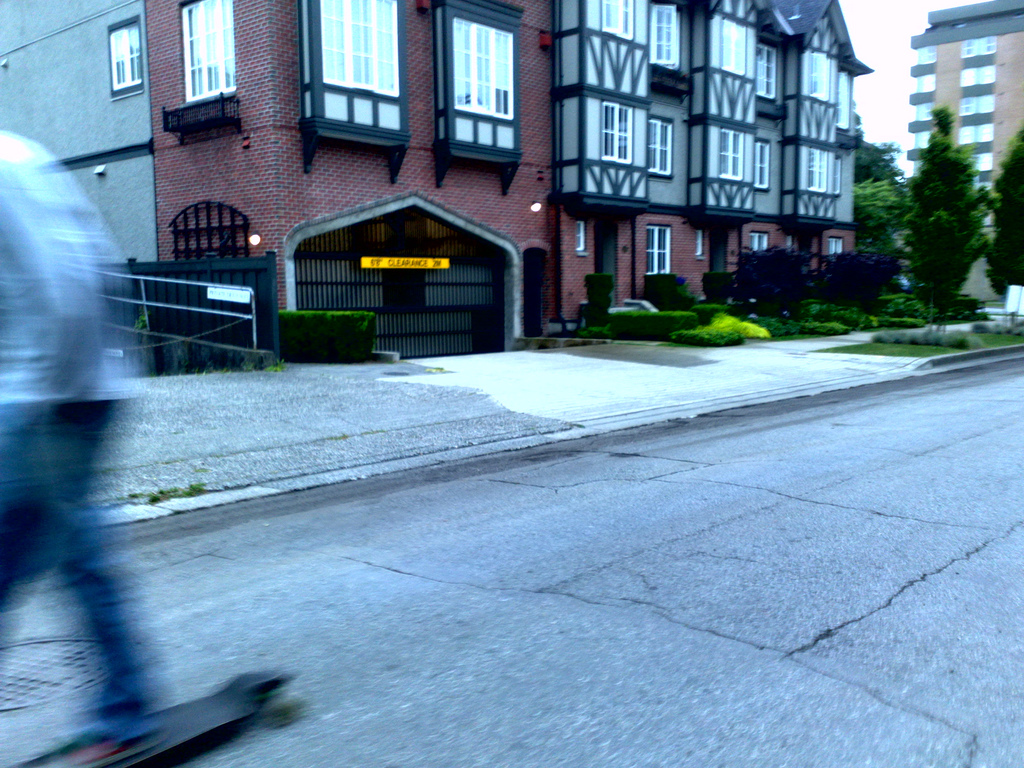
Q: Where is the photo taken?
A: A residential street.